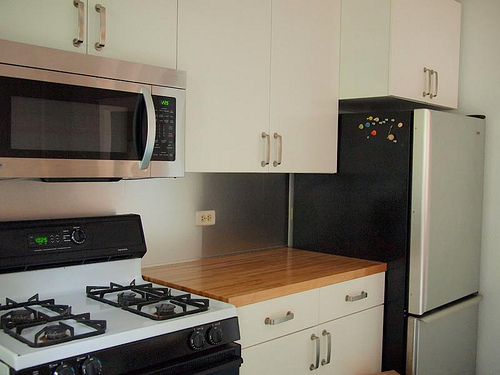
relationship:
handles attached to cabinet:
[68, 1, 115, 52] [179, 14, 352, 168]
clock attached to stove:
[24, 229, 64, 251] [19, 278, 204, 332]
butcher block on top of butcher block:
[142, 256, 325, 293] [142, 245, 385, 310]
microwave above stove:
[7, 90, 179, 177] [19, 278, 204, 332]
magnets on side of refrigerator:
[350, 109, 415, 148] [411, 122, 474, 288]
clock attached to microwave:
[24, 229, 64, 251] [7, 90, 179, 177]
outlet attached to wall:
[197, 208, 219, 226] [211, 185, 282, 194]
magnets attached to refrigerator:
[350, 109, 415, 148] [411, 122, 474, 288]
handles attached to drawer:
[68, 1, 115, 52] [250, 309, 307, 352]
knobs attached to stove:
[184, 327, 228, 346] [19, 278, 204, 332]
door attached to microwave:
[3, 82, 135, 160] [7, 90, 179, 177]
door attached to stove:
[3, 82, 135, 160] [19, 278, 204, 332]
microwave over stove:
[7, 90, 179, 177] [19, 278, 204, 332]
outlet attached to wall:
[180, 204, 236, 226] [211, 185, 282, 194]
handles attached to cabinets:
[68, 1, 115, 52] [256, 305, 370, 355]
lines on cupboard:
[217, 273, 261, 288] [142, 256, 325, 293]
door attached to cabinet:
[3, 82, 135, 160] [179, 14, 352, 168]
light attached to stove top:
[40, 227, 55, 246] [11, 241, 193, 359]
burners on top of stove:
[84, 262, 183, 320] [19, 278, 204, 332]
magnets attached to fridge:
[350, 109, 415, 148] [404, 110, 491, 151]